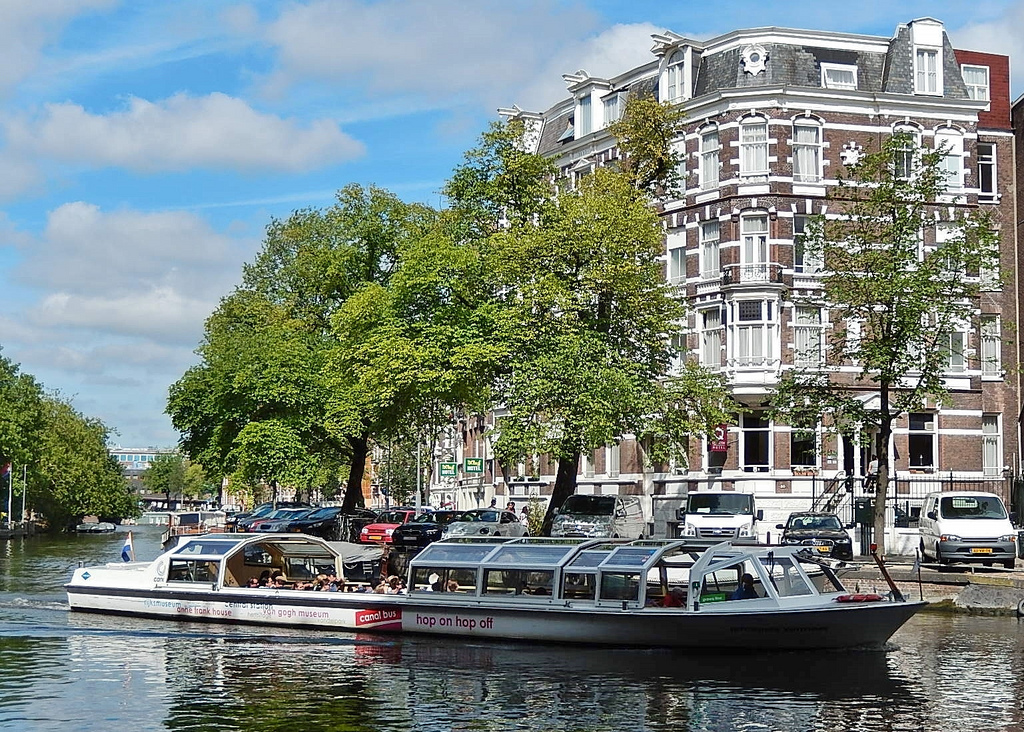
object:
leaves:
[460, 369, 490, 394]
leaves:
[463, 305, 572, 377]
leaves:
[325, 332, 394, 385]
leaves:
[310, 366, 386, 429]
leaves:
[236, 333, 280, 376]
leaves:
[186, 389, 254, 458]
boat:
[64, 530, 930, 650]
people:
[731, 573, 759, 600]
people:
[660, 586, 687, 607]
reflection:
[66, 609, 899, 701]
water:
[0, 508, 1024, 732]